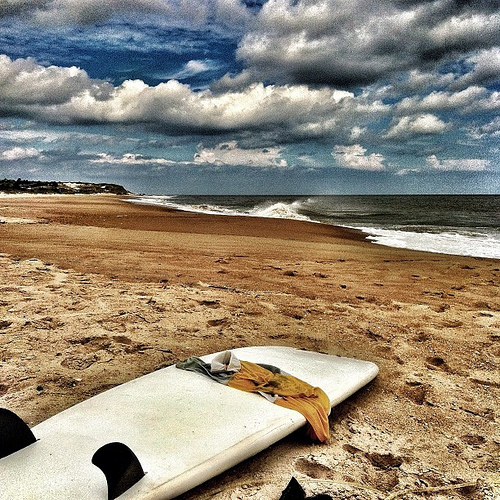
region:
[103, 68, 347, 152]
white cloud in the sky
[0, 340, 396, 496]
white surfboard on the beach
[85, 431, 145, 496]
black fin on white surfboard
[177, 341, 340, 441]
wet clothes on white surfboard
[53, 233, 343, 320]
section of sand on the beach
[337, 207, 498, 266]
waves breaking on the beach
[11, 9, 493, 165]
blue sky filled with clouds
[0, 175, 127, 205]
rock outcropping on beach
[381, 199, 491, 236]
ocean water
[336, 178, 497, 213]
the horizon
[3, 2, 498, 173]
Stormy Weather is Coming Soon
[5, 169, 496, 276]
The Waves are Getting Stronger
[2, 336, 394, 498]
White Surf Board Left Behind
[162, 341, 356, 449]
Article of Clothing Left Behind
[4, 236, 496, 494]
Lots of Footprints means Lots of People were here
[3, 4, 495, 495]
Not a Good Day to be at the Beach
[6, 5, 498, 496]
Stormy Visit to the Ocean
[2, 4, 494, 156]
The Grey Clouds are Storm Clouds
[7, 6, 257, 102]
Pretty Blue Sky in the Middle of Clouds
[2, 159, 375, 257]
Tide has come in and made the sand smooth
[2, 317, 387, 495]
white surf board with black fins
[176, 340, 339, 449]
wet yellow t- shirt on a surf board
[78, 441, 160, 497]
black fin on a surf board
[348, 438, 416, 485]
foot print in the sand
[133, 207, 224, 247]
sand smoothed by the waves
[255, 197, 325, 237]
waves crashing onto the beach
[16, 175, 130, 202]
rocky out cropping into the ocean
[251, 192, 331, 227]
white caps on the waves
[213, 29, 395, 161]
storm clouds rolling in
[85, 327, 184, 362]
sticks on the sand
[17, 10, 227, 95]
white and gray clouds against blue sky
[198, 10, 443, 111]
white and gray clouds against blue sky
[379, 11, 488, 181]
white and gray clouds against blue sky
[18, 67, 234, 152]
white and gray clouds against blue sky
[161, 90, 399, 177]
white and gray clouds against blue sky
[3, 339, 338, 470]
white surf board in brown sand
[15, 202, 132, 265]
brown sand on beach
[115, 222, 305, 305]
brown sand on beach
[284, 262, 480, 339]
brown sand on beach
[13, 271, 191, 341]
brown sand on beach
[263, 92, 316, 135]
part of a cloud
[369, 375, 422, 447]
part of some sand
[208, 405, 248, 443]
part of a board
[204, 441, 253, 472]
edge of a board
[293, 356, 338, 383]
part of a cloth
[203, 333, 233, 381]
part of a collar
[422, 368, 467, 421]
part of a beach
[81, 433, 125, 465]
part of a hooker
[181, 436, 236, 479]
edge of a board